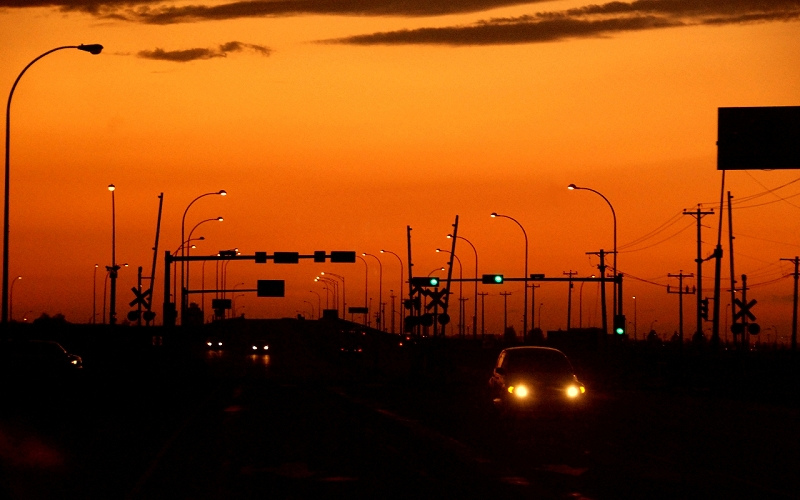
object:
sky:
[0, 0, 799, 332]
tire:
[488, 389, 528, 421]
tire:
[471, 374, 501, 406]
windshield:
[495, 345, 580, 380]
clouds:
[291, 12, 695, 54]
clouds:
[92, 32, 284, 90]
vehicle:
[482, 330, 594, 426]